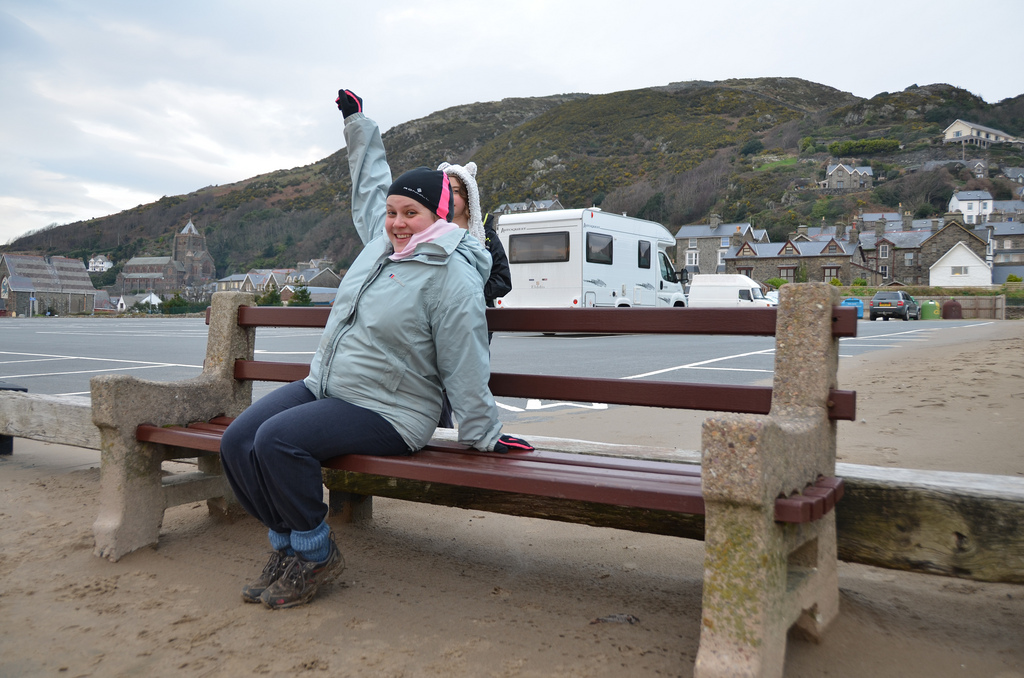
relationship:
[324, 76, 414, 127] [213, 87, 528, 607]
glove on female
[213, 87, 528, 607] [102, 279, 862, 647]
female on bench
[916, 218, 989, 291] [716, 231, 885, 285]
wall on building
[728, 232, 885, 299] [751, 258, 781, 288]
building has wall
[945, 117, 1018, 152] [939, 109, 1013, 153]
building has wall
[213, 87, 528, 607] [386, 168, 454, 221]
female wears accent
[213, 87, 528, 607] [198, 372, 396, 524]
female wears pants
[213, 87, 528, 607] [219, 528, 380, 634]
female wears shoes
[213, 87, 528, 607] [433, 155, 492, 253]
female wears hat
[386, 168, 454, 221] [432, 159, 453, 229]
accent has stripe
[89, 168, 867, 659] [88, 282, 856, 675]
woman/bench on bench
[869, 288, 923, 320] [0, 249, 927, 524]
car in lot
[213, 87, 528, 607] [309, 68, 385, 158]
female wears glove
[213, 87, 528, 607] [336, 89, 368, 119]
female holds up glove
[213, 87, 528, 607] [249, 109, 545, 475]
female wears jacket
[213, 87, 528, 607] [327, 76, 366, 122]
female wears gloves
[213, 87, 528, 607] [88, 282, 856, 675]
female on bench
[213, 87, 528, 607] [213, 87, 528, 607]
female behind female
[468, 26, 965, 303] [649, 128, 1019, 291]
hill has homes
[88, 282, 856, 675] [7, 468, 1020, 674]
bench on sand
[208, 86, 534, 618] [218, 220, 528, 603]
female in clothing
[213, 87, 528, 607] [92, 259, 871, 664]
female on bench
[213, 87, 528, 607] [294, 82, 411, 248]
female has arm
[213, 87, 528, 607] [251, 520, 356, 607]
female has shoes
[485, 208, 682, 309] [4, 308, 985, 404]
bench parked in parking lot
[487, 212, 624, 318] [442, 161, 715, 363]
wall on building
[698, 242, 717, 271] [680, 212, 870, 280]
wall on building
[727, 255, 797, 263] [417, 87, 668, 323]
wall on building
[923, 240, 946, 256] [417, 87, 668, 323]
wall on building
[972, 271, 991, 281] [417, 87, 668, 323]
wall on building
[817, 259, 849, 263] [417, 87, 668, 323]
wall on building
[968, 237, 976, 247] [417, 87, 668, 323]
wall on building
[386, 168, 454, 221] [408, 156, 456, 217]
accent with accent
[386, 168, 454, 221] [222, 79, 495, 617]
accent on person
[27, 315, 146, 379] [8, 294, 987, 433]
white line on lot